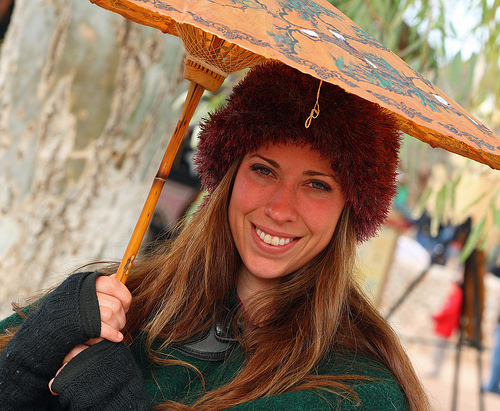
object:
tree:
[0, 0, 203, 319]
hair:
[0, 153, 431, 408]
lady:
[0, 59, 436, 411]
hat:
[192, 59, 403, 244]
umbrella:
[88, 0, 500, 280]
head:
[226, 75, 361, 279]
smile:
[248, 221, 311, 253]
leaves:
[341, 2, 500, 68]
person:
[429, 281, 466, 378]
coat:
[3, 270, 411, 409]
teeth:
[255, 225, 293, 247]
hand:
[73, 272, 134, 344]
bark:
[0, 2, 190, 280]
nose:
[264, 176, 299, 225]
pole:
[115, 85, 206, 282]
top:
[95, 0, 499, 166]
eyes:
[299, 177, 336, 194]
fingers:
[93, 277, 134, 313]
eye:
[247, 163, 280, 185]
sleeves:
[0, 270, 99, 411]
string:
[301, 76, 328, 132]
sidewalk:
[369, 252, 498, 409]